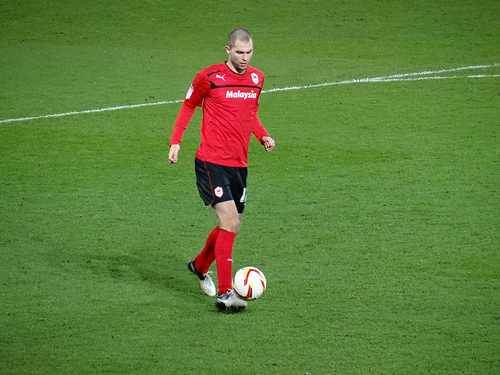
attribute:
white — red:
[234, 263, 273, 307]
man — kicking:
[171, 38, 299, 170]